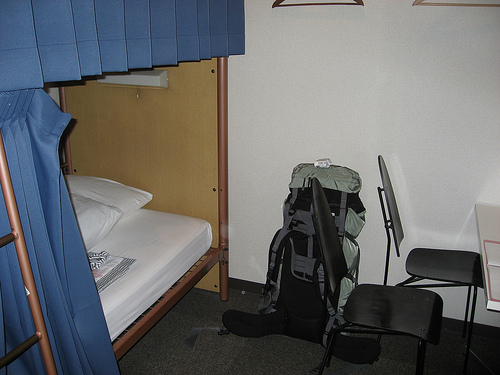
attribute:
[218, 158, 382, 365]
backpack — black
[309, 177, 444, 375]
chair — black, small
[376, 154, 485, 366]
chair — black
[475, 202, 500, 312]
desk — white, white hue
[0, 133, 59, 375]
ladder — brown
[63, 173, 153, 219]
pillow — white color, beautiful, white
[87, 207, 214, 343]
bed — brown, white hue, white color, white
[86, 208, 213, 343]
sheet — white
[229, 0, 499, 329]
wall — eggshell, beautiful, white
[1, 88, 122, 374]
drape — blue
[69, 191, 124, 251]
pillow — white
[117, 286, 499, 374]
carpet — grey